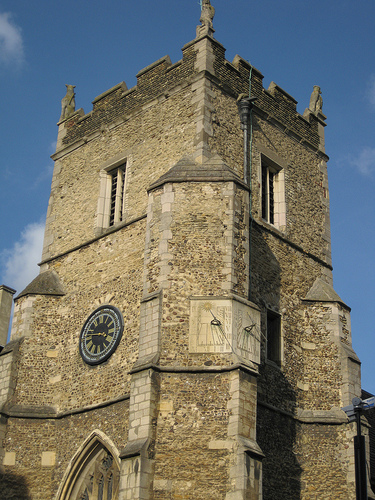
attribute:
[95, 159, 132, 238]
window — rectangle, glass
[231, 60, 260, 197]
gutter — silver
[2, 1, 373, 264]
sky — blue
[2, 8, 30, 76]
cloud — white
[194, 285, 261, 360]
scene — decorative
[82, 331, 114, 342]
time — gold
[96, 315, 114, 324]
numbers — gold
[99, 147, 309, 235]
rectangles — windows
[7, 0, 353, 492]
tower — brick, bricks, castle, stone, brown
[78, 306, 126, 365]
clock — black